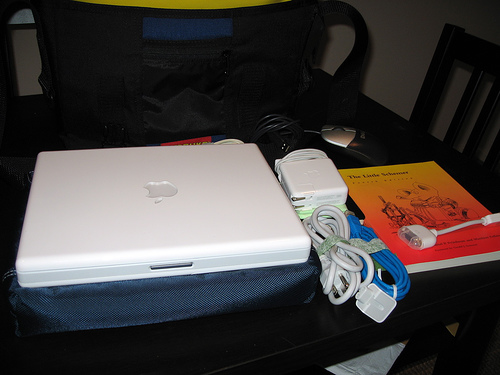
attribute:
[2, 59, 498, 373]
table — wooden, black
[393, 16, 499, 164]
chair — black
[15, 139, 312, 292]
computer — macbook, white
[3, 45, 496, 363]
desk — black, wooden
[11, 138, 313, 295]
laptop — Apple, white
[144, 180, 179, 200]
logo — mac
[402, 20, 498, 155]
chair — wooden, dark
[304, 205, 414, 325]
cables — these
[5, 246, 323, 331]
case — laptop, blue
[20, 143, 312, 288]
laptop — white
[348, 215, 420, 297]
cord — blue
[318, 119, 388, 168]
mouse — computer, silver, black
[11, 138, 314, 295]
macbook — white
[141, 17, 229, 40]
stripe — blue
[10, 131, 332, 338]
laptop — white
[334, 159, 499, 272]
book — yellow, orange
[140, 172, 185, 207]
logo — apple